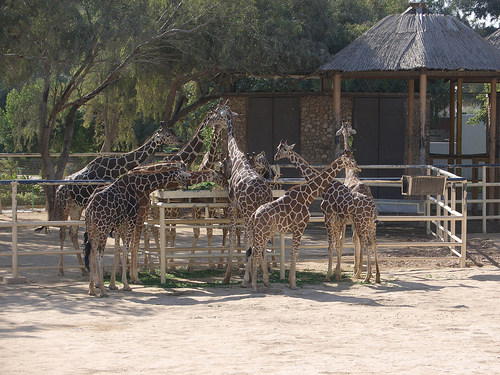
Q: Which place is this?
A: It is a zoo.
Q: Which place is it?
A: It is a zoo.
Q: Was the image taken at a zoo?
A: Yes, it was taken in a zoo.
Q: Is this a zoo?
A: Yes, it is a zoo.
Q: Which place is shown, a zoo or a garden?
A: It is a zoo.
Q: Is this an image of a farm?
A: No, the picture is showing a zoo.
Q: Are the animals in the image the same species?
A: Yes, all the animals are giraffes.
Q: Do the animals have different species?
A: No, all the animals are giraffes.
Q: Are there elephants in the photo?
A: No, there are no elephants.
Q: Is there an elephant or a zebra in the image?
A: No, there are no elephants or zebras.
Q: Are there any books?
A: No, there are no books.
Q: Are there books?
A: No, there are no books.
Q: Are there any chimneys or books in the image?
A: No, there are no books or chimneys.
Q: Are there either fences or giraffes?
A: Yes, there is a giraffe.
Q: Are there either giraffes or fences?
A: Yes, there is a giraffe.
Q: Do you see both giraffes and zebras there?
A: No, there is a giraffe but no zebras.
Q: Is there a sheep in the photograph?
A: No, there is no sheep.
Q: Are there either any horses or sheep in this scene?
A: No, there are no sheep or horses.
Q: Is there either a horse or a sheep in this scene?
A: No, there are no sheep or horses.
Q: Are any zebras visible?
A: No, there are no zebras.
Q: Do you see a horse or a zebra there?
A: No, there are no zebras or horses.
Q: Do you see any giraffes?
A: Yes, there is a giraffe.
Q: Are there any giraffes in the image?
A: Yes, there is a giraffe.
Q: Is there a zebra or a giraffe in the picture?
A: Yes, there is a giraffe.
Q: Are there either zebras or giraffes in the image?
A: Yes, there is a giraffe.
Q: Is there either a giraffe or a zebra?
A: Yes, there is a giraffe.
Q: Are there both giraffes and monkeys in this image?
A: No, there is a giraffe but no monkeys.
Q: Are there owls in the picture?
A: No, there are no owls.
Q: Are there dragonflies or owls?
A: No, there are no owls or dragonflies.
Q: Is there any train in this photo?
A: No, there are no trains.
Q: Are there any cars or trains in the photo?
A: No, there are no trains or cars.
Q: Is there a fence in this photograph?
A: Yes, there is a fence.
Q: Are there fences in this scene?
A: Yes, there is a fence.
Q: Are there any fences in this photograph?
A: Yes, there is a fence.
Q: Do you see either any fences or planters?
A: Yes, there is a fence.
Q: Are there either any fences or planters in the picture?
A: Yes, there is a fence.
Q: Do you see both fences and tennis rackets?
A: No, there is a fence but no rackets.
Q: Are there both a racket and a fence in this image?
A: No, there is a fence but no rackets.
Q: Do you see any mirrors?
A: No, there are no mirrors.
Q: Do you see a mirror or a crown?
A: No, there are no mirrors or crowns.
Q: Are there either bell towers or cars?
A: No, there are no cars or bell towers.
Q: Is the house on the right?
A: Yes, the house is on the right of the image.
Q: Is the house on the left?
A: No, the house is on the right of the image.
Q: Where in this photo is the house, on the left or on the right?
A: The house is on the right of the image.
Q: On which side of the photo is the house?
A: The house is on the right of the image.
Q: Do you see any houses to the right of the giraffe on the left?
A: Yes, there is a house to the right of the giraffe.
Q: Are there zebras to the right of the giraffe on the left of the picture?
A: No, there is a house to the right of the giraffe.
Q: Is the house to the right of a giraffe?
A: Yes, the house is to the right of a giraffe.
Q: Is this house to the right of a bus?
A: No, the house is to the right of a giraffe.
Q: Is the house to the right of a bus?
A: No, the house is to the right of a giraffe.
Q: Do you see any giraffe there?
A: Yes, there is a giraffe.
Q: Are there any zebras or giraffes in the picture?
A: Yes, there is a giraffe.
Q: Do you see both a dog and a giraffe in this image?
A: No, there is a giraffe but no dogs.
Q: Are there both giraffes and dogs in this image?
A: No, there is a giraffe but no dogs.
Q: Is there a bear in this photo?
A: No, there are no bears.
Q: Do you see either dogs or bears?
A: No, there are no bears or dogs.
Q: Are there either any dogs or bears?
A: No, there are no bears or dogs.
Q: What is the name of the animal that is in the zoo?
A: The animal is a giraffe.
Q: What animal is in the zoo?
A: The animal is a giraffe.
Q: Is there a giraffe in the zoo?
A: Yes, there is a giraffe in the zoo.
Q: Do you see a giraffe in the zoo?
A: Yes, there is a giraffe in the zoo.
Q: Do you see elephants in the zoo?
A: No, there is a giraffe in the zoo.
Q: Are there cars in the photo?
A: No, there are no cars.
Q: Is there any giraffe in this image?
A: Yes, there is a giraffe.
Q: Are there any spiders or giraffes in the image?
A: Yes, there is a giraffe.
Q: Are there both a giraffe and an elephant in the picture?
A: No, there is a giraffe but no elephants.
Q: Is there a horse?
A: No, there are no horses.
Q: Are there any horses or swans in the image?
A: No, there are no horses or swans.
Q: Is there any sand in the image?
A: Yes, there is sand.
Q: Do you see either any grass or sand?
A: Yes, there is sand.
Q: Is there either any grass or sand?
A: Yes, there is sand.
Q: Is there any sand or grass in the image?
A: Yes, there is sand.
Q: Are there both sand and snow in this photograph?
A: No, there is sand but no snow.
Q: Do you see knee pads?
A: No, there are no knee pads.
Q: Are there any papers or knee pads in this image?
A: No, there are no knee pads or papers.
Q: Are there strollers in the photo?
A: No, there are no strollers.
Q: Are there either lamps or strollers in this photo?
A: No, there are no strollers or lamps.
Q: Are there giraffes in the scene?
A: Yes, there is a giraffe.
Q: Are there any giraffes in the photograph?
A: Yes, there is a giraffe.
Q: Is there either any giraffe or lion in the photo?
A: Yes, there is a giraffe.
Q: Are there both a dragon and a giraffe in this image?
A: No, there is a giraffe but no dragons.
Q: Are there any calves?
A: No, there are no calves.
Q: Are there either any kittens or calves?
A: No, there are no calves or kittens.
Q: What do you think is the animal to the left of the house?
A: The animal is a giraffe.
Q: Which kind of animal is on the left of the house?
A: The animal is a giraffe.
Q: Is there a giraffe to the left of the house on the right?
A: Yes, there is a giraffe to the left of the house.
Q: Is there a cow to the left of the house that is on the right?
A: No, there is a giraffe to the left of the house.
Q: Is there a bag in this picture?
A: No, there are no bags.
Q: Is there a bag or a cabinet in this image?
A: No, there are no bags or cabinets.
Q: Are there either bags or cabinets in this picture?
A: No, there are no bags or cabinets.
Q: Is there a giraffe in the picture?
A: Yes, there is a giraffe.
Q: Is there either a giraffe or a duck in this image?
A: Yes, there is a giraffe.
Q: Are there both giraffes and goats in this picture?
A: No, there is a giraffe but no goats.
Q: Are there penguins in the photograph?
A: No, there are no penguins.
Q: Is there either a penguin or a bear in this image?
A: No, there are no penguins or bears.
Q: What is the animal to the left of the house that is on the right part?
A: The animal is a giraffe.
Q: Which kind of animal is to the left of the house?
A: The animal is a giraffe.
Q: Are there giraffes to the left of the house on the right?
A: Yes, there is a giraffe to the left of the house.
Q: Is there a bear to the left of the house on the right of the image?
A: No, there is a giraffe to the left of the house.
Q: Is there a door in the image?
A: Yes, there is a door.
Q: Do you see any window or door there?
A: Yes, there is a door.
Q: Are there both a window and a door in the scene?
A: No, there is a door but no windows.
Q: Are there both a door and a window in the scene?
A: No, there is a door but no windows.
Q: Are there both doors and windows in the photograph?
A: No, there is a door but no windows.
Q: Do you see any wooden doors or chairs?
A: Yes, there is a wood door.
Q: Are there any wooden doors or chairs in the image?
A: Yes, there is a wood door.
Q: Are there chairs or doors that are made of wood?
A: Yes, the door is made of wood.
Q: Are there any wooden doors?
A: Yes, there is a wood door.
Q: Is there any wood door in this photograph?
A: Yes, there is a wood door.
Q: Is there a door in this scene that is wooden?
A: Yes, there is a door that is wooden.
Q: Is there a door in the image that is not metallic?
A: Yes, there is a wooden door.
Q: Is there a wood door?
A: Yes, there is a door that is made of wood.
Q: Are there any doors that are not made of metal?
A: Yes, there is a door that is made of wood.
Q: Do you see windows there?
A: No, there are no windows.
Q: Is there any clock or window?
A: No, there are no windows or clocks.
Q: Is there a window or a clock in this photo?
A: No, there are no windows or clocks.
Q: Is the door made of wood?
A: Yes, the door is made of wood.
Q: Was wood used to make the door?
A: Yes, the door is made of wood.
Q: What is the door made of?
A: The door is made of wood.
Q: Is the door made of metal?
A: No, the door is made of wood.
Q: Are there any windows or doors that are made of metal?
A: No, there is a door but it is made of wood.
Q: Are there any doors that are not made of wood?
A: No, there is a door but it is made of wood.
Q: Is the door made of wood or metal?
A: The door is made of wood.